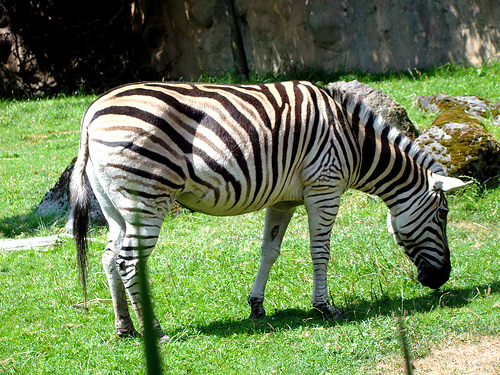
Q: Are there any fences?
A: No, there are no fences.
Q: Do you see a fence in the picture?
A: No, there are no fences.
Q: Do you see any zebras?
A: Yes, there is a zebra.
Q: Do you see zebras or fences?
A: Yes, there is a zebra.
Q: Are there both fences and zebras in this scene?
A: No, there is a zebra but no fences.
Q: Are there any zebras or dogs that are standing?
A: Yes, the zebra is standing.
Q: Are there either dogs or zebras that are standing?
A: Yes, the zebra is standing.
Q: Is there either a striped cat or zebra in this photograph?
A: Yes, there is a striped zebra.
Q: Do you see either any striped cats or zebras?
A: Yes, there is a striped zebra.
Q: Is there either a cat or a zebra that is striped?
A: Yes, the zebra is striped.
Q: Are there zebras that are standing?
A: Yes, there is a zebra that is standing.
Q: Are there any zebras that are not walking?
A: Yes, there is a zebra that is standing.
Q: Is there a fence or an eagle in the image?
A: No, there are no fences or eagles.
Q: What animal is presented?
A: The animal is a zebra.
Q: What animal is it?
A: The animal is a zebra.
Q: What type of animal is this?
A: That is a zebra.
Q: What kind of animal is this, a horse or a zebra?
A: That is a zebra.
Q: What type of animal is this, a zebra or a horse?
A: That is a zebra.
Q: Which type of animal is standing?
A: The animal is a zebra.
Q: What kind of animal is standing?
A: The animal is a zebra.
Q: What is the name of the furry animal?
A: The animal is a zebra.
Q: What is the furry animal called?
A: The animal is a zebra.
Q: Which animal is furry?
A: The animal is a zebra.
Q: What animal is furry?
A: The animal is a zebra.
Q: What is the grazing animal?
A: The animal is a zebra.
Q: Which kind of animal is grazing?
A: The animal is a zebra.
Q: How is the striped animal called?
A: The animal is a zebra.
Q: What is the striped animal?
A: The animal is a zebra.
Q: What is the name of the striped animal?
A: The animal is a zebra.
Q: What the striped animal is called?
A: The animal is a zebra.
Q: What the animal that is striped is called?
A: The animal is a zebra.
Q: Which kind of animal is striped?
A: The animal is a zebra.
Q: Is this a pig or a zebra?
A: This is a zebra.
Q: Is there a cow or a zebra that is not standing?
A: No, there is a zebra but it is standing.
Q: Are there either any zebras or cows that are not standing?
A: No, there is a zebra but it is standing.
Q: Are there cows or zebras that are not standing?
A: No, there is a zebra but it is standing.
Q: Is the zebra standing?
A: Yes, the zebra is standing.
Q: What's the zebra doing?
A: The zebra is standing.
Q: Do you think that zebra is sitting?
A: No, the zebra is standing.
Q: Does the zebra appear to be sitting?
A: No, the zebra is standing.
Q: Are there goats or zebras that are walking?
A: No, there is a zebra but it is standing.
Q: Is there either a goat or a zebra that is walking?
A: No, there is a zebra but it is standing.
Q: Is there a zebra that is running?
A: No, there is a zebra but it is standing.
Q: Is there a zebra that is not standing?
A: No, there is a zebra but it is standing.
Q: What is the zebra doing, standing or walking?
A: The zebra is standing.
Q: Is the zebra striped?
A: Yes, the zebra is striped.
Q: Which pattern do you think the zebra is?
A: The zebra is striped.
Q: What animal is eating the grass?
A: The animal is a zebra.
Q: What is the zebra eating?
A: The zebra is eating grass.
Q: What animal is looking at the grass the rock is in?
A: The animal is a zebra.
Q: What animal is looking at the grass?
A: The animal is a zebra.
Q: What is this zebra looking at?
A: The zebra is looking at the grass.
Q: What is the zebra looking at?
A: The zebra is looking at the grass.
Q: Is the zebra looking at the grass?
A: Yes, the zebra is looking at the grass.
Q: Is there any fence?
A: No, there are no fences.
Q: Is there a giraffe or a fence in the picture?
A: No, there are no fences or giraffes.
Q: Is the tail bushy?
A: Yes, the tail is bushy.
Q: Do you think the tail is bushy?
A: Yes, the tail is bushy.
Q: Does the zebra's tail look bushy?
A: Yes, the tail is bushy.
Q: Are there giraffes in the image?
A: No, there are no giraffes.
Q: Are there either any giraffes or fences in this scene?
A: No, there are no giraffes or fences.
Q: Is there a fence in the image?
A: No, there are no fences.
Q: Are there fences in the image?
A: No, there are no fences.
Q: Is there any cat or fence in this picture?
A: No, there are no fences or cats.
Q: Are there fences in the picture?
A: No, there are no fences.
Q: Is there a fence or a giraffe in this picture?
A: No, there are no fences or giraffes.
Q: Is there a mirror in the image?
A: No, there are no mirrors.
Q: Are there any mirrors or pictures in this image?
A: No, there are no mirrors or pictures.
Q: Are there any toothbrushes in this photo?
A: No, there are no toothbrushes.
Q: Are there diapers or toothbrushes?
A: No, there are no toothbrushes or diapers.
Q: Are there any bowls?
A: No, there are no bowls.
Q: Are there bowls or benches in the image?
A: No, there are no bowls or benches.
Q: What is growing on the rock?
A: The moss is growing on the rock.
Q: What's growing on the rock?
A: The moss is growing on the rock.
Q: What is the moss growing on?
A: The moss is growing on the rock.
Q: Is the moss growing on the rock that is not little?
A: Yes, the moss is growing on the rock.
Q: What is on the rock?
A: The moss is on the rock.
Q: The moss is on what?
A: The moss is on the rock.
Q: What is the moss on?
A: The moss is on the rock.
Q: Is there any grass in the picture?
A: Yes, there is grass.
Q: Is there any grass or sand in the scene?
A: Yes, there is grass.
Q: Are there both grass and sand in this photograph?
A: No, there is grass but no sand.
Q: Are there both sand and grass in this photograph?
A: No, there is grass but no sand.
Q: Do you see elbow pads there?
A: No, there are no elbow pads.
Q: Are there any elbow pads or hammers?
A: No, there are no elbow pads or hammers.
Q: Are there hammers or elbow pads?
A: No, there are no elbow pads or hammers.